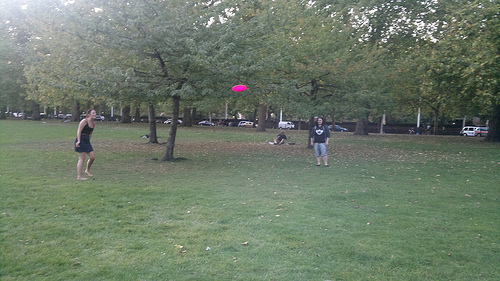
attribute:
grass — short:
[4, 120, 500, 278]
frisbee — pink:
[231, 82, 249, 95]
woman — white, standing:
[305, 114, 340, 169]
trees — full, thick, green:
[23, 1, 496, 151]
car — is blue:
[326, 127, 348, 132]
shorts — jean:
[310, 140, 328, 159]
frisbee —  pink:
[231, 79, 246, 93]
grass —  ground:
[13, 174, 481, 271]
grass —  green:
[6, 136, 496, 275]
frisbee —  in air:
[230, 82, 245, 92]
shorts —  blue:
[312, 143, 328, 161]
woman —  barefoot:
[74, 101, 99, 181]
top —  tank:
[80, 112, 96, 140]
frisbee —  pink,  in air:
[228, 83, 243, 94]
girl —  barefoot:
[74, 102, 96, 182]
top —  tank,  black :
[72, 115, 95, 145]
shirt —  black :
[72, 113, 97, 143]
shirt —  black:
[309, 123, 329, 141]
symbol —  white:
[311, 127, 322, 136]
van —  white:
[274, 118, 294, 129]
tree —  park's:
[23, 6, 296, 159]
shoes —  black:
[316, 158, 328, 169]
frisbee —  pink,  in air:
[231, 78, 246, 92]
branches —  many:
[150, 40, 194, 100]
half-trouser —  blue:
[312, 140, 330, 159]